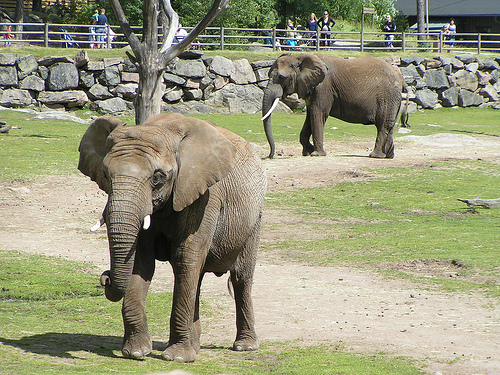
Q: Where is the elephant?
A: Grass.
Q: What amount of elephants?
A: Two.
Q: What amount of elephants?
A: Two.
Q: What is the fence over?
A: Wall.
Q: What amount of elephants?
A: Two.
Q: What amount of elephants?
A: Two.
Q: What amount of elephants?
A: Two.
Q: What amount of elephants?
A: Two.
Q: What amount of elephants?
A: Two.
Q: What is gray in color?
A: The animals.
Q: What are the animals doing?
A: Standing.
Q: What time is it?
A: Afternoon.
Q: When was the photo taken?
A: During the daytime.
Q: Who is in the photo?
A: Some people.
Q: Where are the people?
A: In the distance.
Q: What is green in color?
A: Grass.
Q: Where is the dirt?
A: On the ground.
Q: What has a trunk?
A: The elephant.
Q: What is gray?
A: Elephants.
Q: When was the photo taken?
A: During the day.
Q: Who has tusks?
A: Two elephants.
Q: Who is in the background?
A: People.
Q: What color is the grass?
A: Green.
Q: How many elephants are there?
A: Two.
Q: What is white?
A: Elephant's tusks.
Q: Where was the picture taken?
A: At a zoo.